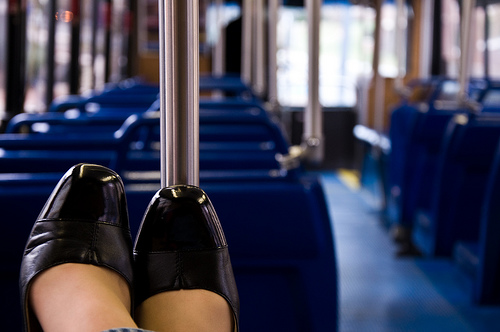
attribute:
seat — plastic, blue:
[0, 174, 338, 331]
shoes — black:
[36, 161, 233, 303]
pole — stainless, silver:
[159, 0, 199, 190]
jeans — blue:
[93, 328, 155, 330]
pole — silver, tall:
[443, 17, 477, 99]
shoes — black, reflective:
[18, 161, 133, 329]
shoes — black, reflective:
[129, 177, 243, 329]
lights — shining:
[278, 12, 362, 96]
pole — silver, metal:
[151, 2, 209, 185]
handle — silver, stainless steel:
[151, 15, 205, 170]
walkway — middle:
[319, 170, 499, 330]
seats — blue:
[347, 74, 497, 280]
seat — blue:
[396, 107, 490, 241]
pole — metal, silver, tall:
[151, 11, 206, 187]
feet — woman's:
[23, 264, 237, 328]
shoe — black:
[133, 182, 241, 330]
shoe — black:
[17, 162, 134, 329]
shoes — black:
[15, 140, 236, 290]